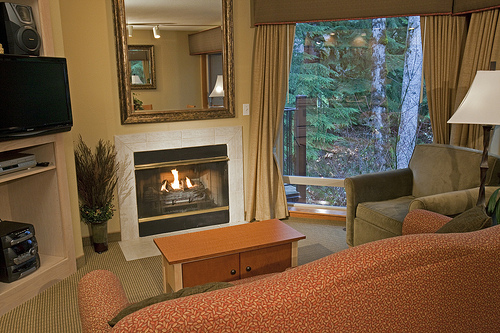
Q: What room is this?
A: Living room.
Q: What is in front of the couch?
A: Fireplace.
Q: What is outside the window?
A: Tree.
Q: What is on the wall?
A: Mirror.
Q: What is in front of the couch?
A: Coffee table.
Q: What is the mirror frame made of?
A: Wood.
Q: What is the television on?
A: Entertainment stand.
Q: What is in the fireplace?
A: Fire.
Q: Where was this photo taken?
A: In a living room.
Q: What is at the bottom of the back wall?
A: A fireplace.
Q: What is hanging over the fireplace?
A: A mirror.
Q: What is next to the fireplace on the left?
A: A plant.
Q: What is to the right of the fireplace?
A: A window.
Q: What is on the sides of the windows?
A: Drapes.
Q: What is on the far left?
A: A shelf.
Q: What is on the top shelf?
A: A tv.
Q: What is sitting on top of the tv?
A: A speaker.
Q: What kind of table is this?
A: Coffee.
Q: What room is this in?
A: Living room.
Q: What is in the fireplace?
A: Fire.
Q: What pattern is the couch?
A: Sprinkle.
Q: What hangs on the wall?
A: Mirror.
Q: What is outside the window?
A: Trees.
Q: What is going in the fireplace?
A: A fire.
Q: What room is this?
A: The living room.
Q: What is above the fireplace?
A: A mirror.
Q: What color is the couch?
A: Red.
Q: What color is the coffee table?
A: Brown.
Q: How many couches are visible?
A: One.